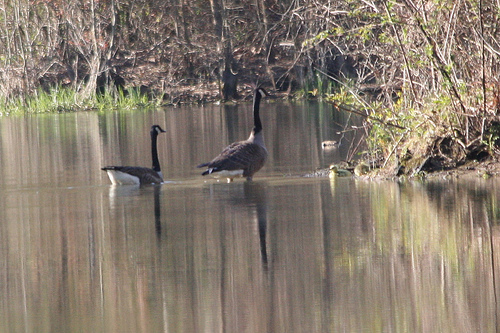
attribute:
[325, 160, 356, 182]
duck — baby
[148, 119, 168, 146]
head — black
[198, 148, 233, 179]
feather — bird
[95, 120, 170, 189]
swan — white, black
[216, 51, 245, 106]
tree trunk — dead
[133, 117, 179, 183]
bird — peck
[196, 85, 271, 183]
bird — body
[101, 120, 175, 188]
animal — dark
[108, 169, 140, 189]
accents — white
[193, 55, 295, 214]
bird — body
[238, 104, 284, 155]
neck — black